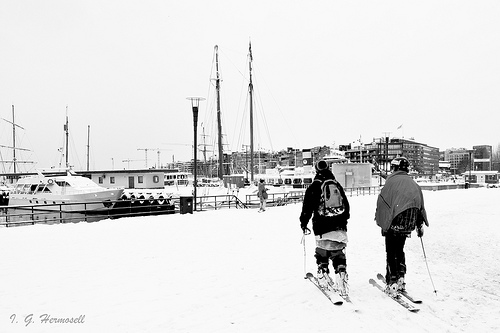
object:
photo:
[0, 0, 500, 333]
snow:
[0, 188, 500, 333]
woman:
[256, 178, 268, 213]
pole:
[248, 36, 254, 181]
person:
[300, 160, 351, 291]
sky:
[0, 0, 500, 173]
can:
[180, 195, 194, 214]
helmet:
[390, 157, 411, 173]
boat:
[0, 168, 126, 212]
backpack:
[314, 178, 346, 217]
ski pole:
[416, 220, 439, 297]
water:
[0, 207, 175, 228]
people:
[374, 157, 424, 298]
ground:
[0, 187, 500, 333]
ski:
[306, 272, 344, 305]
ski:
[316, 270, 360, 313]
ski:
[369, 278, 421, 311]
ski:
[376, 273, 422, 303]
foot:
[316, 276, 330, 289]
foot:
[333, 285, 350, 297]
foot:
[385, 286, 399, 297]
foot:
[395, 282, 406, 291]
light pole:
[192, 107, 199, 211]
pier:
[0, 169, 378, 211]